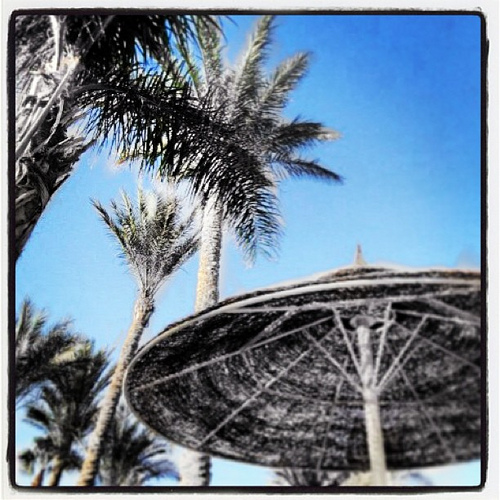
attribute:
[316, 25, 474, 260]
sky — Part , blue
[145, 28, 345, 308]
tree — palm tree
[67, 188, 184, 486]
tree — palm tree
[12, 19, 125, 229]
tree — palm tree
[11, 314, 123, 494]
tree — palm tree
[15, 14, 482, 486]
blue sky — bright blue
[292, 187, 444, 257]
clouds — white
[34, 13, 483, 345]
sky — blue, Part ,  blue 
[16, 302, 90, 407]
tree — black, white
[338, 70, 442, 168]
sky — blue, Part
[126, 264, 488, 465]
umbrella — beach umbrella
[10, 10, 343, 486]
trees — tall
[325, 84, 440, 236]
sky — blue, Part 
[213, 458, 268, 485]
sky — blue, Part 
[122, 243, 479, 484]
umbrella — black, white, beach umbrella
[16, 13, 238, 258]
tree — palm tree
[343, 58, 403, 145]
sky — Part , blue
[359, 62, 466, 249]
sky — blue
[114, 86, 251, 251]
tree — black, white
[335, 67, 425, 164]
sky — bright blue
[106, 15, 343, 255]
leaves — big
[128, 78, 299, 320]
tree — black, white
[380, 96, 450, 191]
sky — Part , blue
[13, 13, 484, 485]
sky — bright blue, blue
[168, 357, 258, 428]
umbrella — thatched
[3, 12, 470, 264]
sky — Part, blue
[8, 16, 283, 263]
tree — white, black, palm tree